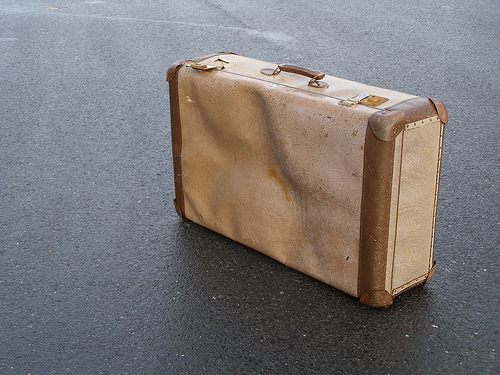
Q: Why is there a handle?
A: To carry the suitcase.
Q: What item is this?
A: A suitcase.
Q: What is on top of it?
A: A handle.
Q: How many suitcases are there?
A: One.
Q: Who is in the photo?
A: Nobody.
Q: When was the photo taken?
A: Daytime.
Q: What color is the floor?
A: Black.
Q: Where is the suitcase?
A: On the ground.